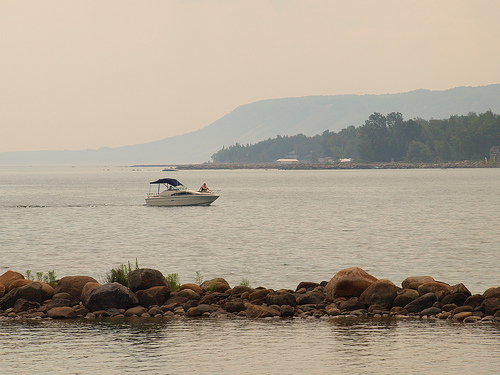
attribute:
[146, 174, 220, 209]
boat — small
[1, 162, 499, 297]
bay — body, calm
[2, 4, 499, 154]
sky — overcast, hazy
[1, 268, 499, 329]
jetty — different, large, small, mixed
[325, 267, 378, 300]
rock — brown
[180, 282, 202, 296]
rock — brown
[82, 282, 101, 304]
rock — brown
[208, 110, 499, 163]
forest — thick, green, growing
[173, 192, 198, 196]
windows — small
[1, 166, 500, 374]
water — calm